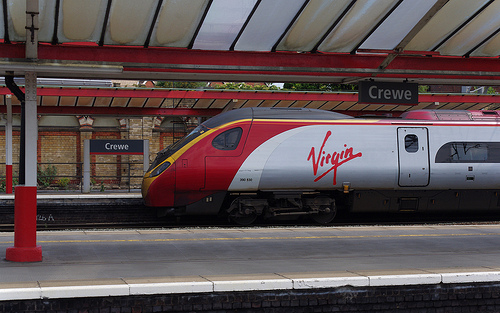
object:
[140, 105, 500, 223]
train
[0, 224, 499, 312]
platform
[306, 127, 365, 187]
logo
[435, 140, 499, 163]
window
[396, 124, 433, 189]
door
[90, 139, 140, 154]
sign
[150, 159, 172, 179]
headlight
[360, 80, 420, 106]
sign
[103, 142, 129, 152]
crewe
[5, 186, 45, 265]
pylon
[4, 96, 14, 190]
beam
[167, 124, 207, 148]
windshield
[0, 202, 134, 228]
subway